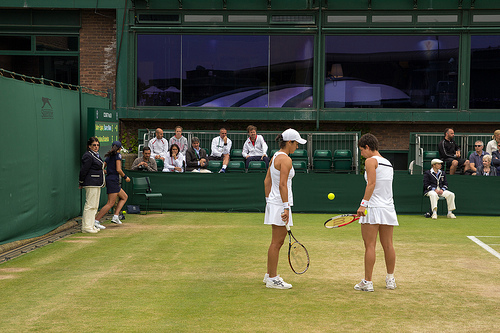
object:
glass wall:
[127, 6, 499, 122]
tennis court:
[0, 210, 500, 332]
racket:
[281, 210, 310, 274]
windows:
[135, 41, 500, 109]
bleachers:
[125, 129, 359, 173]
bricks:
[85, 35, 99, 39]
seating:
[227, 159, 247, 173]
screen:
[122, 171, 500, 215]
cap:
[283, 127, 309, 144]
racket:
[324, 214, 364, 229]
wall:
[7, 81, 79, 229]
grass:
[419, 220, 456, 325]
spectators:
[167, 126, 188, 156]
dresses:
[263, 202, 292, 226]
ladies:
[262, 128, 307, 290]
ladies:
[94, 141, 130, 229]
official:
[422, 158, 457, 220]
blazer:
[421, 168, 449, 196]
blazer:
[79, 149, 107, 188]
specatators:
[184, 136, 209, 172]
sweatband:
[359, 198, 369, 208]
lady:
[353, 133, 399, 292]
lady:
[79, 136, 106, 233]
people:
[159, 143, 184, 172]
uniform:
[357, 155, 399, 226]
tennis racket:
[281, 212, 310, 275]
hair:
[357, 133, 378, 153]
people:
[130, 146, 158, 172]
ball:
[327, 192, 336, 200]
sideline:
[0, 196, 123, 266]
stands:
[275, 119, 498, 219]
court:
[0, 208, 499, 333]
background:
[81, 66, 465, 195]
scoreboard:
[87, 107, 120, 144]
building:
[2, 1, 498, 214]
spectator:
[210, 128, 233, 173]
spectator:
[146, 128, 169, 162]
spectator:
[241, 125, 268, 167]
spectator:
[169, 126, 189, 155]